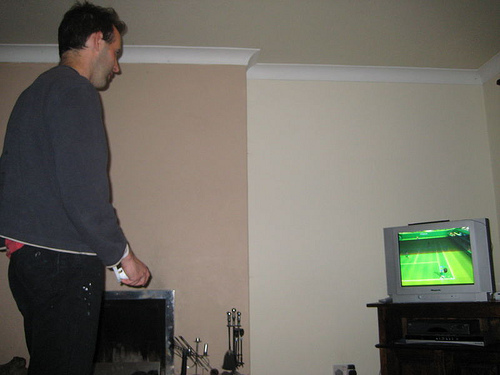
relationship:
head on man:
[56, 2, 126, 88] [1, 2, 159, 369]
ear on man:
[90, 28, 104, 53] [1, 2, 159, 369]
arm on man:
[57, 72, 131, 266] [1, 2, 159, 369]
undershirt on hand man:
[4, 236, 21, 255] [0, 1, 152, 375]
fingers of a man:
[120, 273, 154, 289] [1, 2, 159, 369]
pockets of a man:
[18, 260, 74, 315] [0, 2, 177, 372]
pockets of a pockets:
[71, 255, 102, 311] [18, 260, 74, 315]